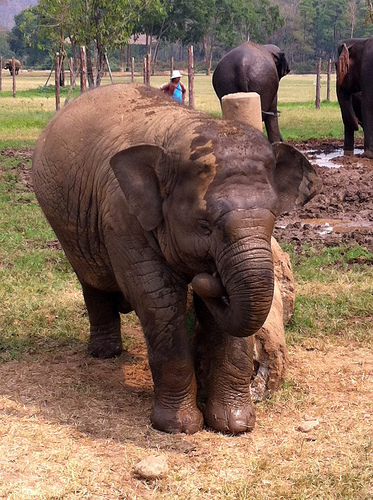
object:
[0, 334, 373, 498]
brown grass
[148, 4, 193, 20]
leaves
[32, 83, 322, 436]
elephant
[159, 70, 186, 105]
man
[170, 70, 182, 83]
hat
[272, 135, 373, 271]
mud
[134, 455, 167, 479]
rocks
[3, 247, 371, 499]
ground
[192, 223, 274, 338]
elephant trunk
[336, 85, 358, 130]
elephant trunk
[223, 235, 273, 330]
wrinkles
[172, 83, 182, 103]
shirt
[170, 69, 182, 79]
cap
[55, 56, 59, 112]
wooden posts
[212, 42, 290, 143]
animal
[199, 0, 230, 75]
tree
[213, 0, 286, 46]
tree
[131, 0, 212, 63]
tree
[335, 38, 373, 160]
elephant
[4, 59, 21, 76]
elephant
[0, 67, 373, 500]
grass